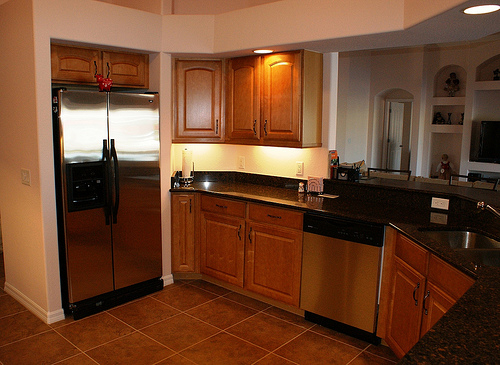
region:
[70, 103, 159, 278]
The refrigerator is stainless steel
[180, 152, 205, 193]
A candle on the counter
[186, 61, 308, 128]
Cabinets in the kitchen.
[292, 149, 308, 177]
Power outlet on the wall.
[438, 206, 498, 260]
Sink in the kitchen.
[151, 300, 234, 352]
The floor is tiled.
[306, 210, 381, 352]
Dishwasher between the cabinet.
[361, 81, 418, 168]
Entrance to the next room.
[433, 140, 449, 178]
A doll on the wall shelf.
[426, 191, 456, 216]
Power outgae on the counter.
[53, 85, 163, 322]
a stainless steel refrigerator in the kitchen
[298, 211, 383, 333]
a brown and black dishwasher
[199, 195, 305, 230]
two drawers under the countertop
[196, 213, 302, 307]
two cabinet doors under the drawers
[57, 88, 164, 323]
a side by side door on the refrigerator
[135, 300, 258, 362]
brown tiles on the kitchen's floor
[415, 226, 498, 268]
a double sink in the kitchen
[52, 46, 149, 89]
two small wooden cabinets above the refrigerator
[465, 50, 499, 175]
a wall entertainment center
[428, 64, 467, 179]
dolls on the shelves beside the wall entertainment center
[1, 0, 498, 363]
This is a kitchen scene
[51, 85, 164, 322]
A refrigerator and freezer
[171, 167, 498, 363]
A kitchen counter top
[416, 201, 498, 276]
This is the kitchen sink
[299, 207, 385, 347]
An electric dishwasher is under the counter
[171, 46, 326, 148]
These are overhead cabinets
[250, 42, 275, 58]
A light is above the cabinets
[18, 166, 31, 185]
A light switch is on the wall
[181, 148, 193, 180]
A roll of paper towels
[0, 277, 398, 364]
The floor is covered in tiles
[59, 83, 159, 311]
the stainless steel fridge doors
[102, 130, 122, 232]
the black handles of the fridge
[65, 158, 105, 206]
the water and ice maker on the door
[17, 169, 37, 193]
the light switch on the wall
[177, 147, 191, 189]
the roll of paper towels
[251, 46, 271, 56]
the round light on the ceiling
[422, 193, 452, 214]
the electrical socket by the sink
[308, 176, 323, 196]
the napkins in the holder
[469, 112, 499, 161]
the TV on the wall shelf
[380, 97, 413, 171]
the open door in the archway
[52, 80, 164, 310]
a large stainless steel refrigerator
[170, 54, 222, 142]
a brown cabinet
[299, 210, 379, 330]
a stainless steel dishwasher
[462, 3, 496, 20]
part of a ceiling light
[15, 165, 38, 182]
a white light switch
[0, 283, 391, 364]
kitchen tile floor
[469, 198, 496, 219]
part of sink faucet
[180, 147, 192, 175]
a roll of paper towels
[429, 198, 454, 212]
a white wall outlet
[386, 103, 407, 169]
a white door